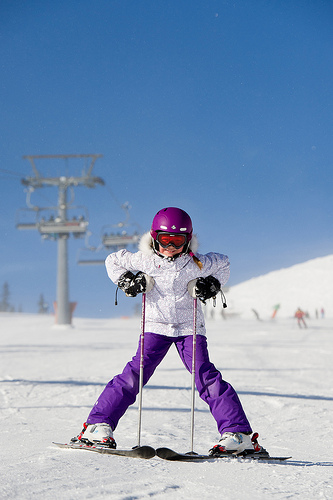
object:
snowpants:
[84, 332, 253, 435]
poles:
[190, 299, 197, 455]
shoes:
[81, 421, 117, 450]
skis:
[50, 441, 157, 461]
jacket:
[104, 230, 230, 339]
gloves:
[187, 275, 227, 309]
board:
[154, 444, 292, 461]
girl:
[69, 204, 269, 457]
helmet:
[150, 206, 193, 235]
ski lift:
[36, 211, 89, 246]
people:
[294, 306, 310, 329]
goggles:
[156, 232, 189, 250]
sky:
[0, 0, 333, 317]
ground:
[0, 315, 332, 500]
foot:
[79, 418, 116, 450]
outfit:
[51, 237, 294, 463]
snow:
[0, 257, 333, 499]